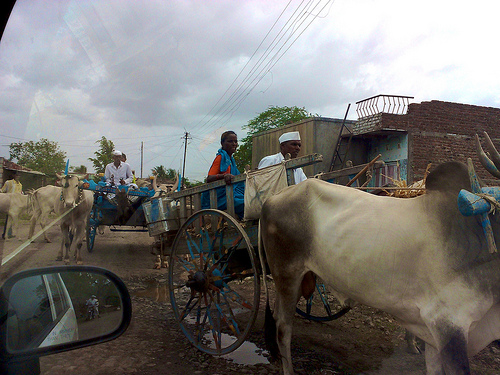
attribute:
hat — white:
[279, 124, 296, 145]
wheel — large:
[168, 222, 292, 343]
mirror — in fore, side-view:
[8, 253, 127, 352]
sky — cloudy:
[23, 9, 485, 85]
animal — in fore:
[263, 170, 498, 366]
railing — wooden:
[156, 152, 320, 217]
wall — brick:
[365, 106, 496, 177]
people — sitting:
[197, 125, 312, 192]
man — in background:
[110, 153, 145, 187]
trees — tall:
[10, 134, 206, 186]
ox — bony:
[271, 158, 485, 375]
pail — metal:
[134, 194, 189, 238]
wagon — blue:
[72, 165, 172, 247]